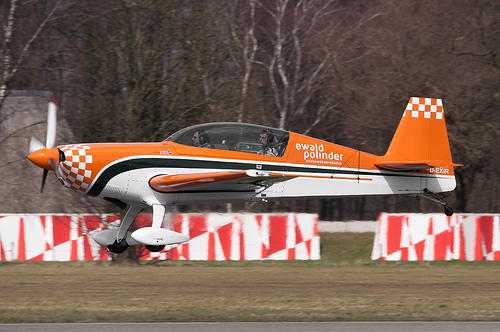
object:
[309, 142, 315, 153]
letter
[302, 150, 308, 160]
letter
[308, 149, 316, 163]
letter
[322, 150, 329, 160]
letter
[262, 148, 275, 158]
shirt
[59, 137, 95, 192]
pattern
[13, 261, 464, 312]
grass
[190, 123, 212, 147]
man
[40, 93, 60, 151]
blade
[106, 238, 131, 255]
wheel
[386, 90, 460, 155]
stabilizer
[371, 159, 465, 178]
stabilizer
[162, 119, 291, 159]
cockpit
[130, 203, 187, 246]
structure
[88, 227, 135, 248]
structure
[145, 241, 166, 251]
wheel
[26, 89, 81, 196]
propeller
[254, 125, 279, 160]
man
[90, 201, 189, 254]
gear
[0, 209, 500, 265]
banner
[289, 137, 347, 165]
name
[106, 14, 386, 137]
trees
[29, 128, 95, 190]
nose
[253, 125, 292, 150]
seat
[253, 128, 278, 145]
headphones.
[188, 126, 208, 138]
headphones .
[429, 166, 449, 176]
letters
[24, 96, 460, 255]
airplane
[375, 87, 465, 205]
tail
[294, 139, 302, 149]
letters